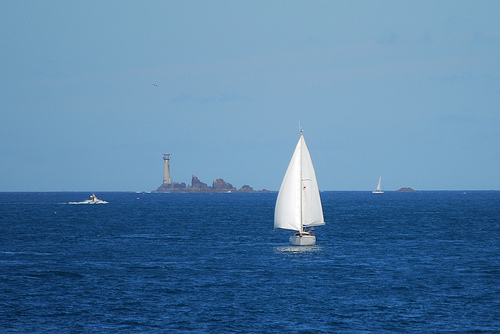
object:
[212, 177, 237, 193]
building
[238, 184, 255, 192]
building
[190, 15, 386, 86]
clouds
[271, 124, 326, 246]
boat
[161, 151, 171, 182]
lighthouse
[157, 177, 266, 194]
land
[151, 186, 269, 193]
island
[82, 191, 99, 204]
jetski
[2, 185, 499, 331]
sea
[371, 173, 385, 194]
boat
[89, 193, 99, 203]
boat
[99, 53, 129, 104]
white clouds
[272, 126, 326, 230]
sail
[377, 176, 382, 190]
sail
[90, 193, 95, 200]
person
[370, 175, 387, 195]
sailboat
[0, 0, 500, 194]
sky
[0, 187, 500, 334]
water